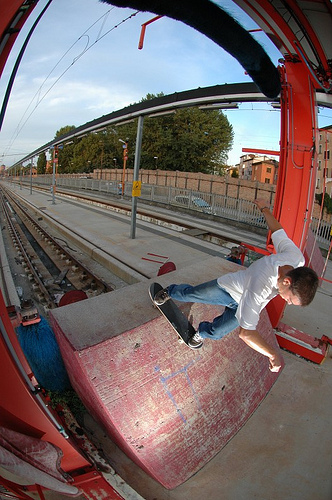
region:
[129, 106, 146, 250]
a metal post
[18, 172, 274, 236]
a metal railing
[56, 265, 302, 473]
a red painted ramp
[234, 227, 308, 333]
a white shirt on a boy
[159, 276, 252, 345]
blue jeans on a boy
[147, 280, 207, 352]
a skateboard on the edge of a ramp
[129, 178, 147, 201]
a yellow sign on a post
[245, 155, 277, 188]
a red brick building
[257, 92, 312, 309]
a red metal support post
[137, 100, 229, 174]
a tree behind a fence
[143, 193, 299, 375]
Skateboarder going down ramp.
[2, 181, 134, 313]
Train tracks behind skater.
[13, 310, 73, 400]
Blue brush next to ramp.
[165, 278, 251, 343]
Jeans worn by skater.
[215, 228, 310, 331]
White tshirt being worn.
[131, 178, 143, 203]
Yellow sign on pole.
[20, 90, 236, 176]
Trees in the background.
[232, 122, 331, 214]
Building in the background.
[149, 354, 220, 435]
Blue marking on ramp.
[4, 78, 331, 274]
Rails and poles for trains.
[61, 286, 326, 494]
the ramp is red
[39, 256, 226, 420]
the ramp is red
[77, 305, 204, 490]
the ramp is red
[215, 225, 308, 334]
a white shirt on a man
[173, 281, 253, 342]
blue jeans on a ramp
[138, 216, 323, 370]
a man going down a ramp on a skateboard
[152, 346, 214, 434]
blue lines painted on a red ramp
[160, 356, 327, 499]
a concrete floor below a ramp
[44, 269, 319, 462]
a red painted concrete ramp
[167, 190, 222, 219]
a car along the road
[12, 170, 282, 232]
a fence along a road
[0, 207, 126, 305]
train tracks running alongside a walkway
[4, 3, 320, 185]
a blue and white sky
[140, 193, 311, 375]
a boy riding a skateboard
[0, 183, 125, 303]
a set of train tracks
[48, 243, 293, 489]
a red train stopping block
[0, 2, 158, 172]
overhead electrical wires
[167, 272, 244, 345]
a pair of blue jeans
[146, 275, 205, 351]
a black skateboard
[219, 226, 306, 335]
a white men's t-shirt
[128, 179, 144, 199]
a yellow pole mounted sign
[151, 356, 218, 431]
worn blue graffiti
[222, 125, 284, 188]
buildings in the distance